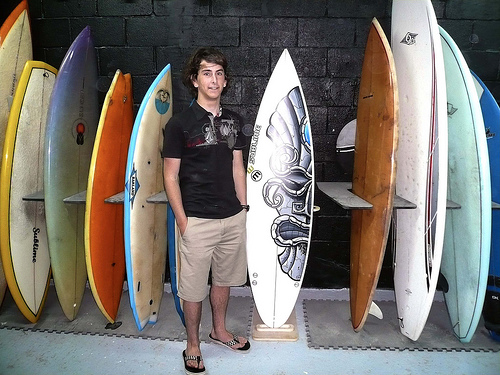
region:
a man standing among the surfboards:
[160, 49, 259, 372]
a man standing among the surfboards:
[28, 28, 413, 362]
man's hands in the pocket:
[153, 46, 257, 297]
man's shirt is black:
[143, 63, 273, 253]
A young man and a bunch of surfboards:
[26, 17, 404, 317]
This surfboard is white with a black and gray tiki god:
[249, 47, 317, 334]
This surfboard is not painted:
[328, 12, 402, 347]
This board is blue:
[470, 62, 498, 125]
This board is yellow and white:
[8, 58, 47, 327]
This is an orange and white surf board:
[1, 5, 46, 62]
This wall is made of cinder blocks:
[204, 3, 346, 42]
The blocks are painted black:
[282, 14, 348, 56]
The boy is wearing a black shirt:
[171, 54, 250, 156]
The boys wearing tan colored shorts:
[171, 76, 251, 301]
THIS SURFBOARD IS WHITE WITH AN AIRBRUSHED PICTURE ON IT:
[230, 42, 320, 349]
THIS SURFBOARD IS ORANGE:
[83, 62, 138, 332]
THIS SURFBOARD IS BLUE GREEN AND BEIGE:
[45, 27, 100, 337]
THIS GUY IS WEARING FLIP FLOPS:
[177, 320, 252, 371]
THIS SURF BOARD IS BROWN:
[330, 21, 397, 333]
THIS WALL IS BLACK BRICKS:
[0, 2, 496, 289]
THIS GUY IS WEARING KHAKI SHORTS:
[162, 210, 264, 318]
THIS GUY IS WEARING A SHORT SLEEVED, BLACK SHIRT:
[160, 100, 255, 221]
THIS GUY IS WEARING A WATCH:
[235, 190, 263, 220]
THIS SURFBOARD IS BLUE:
[468, 68, 498, 323]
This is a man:
[148, 66, 275, 357]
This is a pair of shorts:
[148, 190, 265, 270]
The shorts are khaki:
[165, 195, 292, 347]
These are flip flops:
[166, 341, 284, 373]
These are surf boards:
[184, 75, 499, 265]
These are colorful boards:
[13, 59, 245, 364]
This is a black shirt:
[161, 114, 219, 228]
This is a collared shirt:
[156, 101, 236, 133]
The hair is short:
[183, 26, 249, 123]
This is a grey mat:
[295, 291, 361, 370]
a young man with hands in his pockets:
[159, 49, 249, 373]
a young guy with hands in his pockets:
[167, 54, 248, 374]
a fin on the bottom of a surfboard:
[367, 302, 384, 322]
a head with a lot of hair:
[183, 46, 234, 98]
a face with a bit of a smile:
[196, 56, 226, 97]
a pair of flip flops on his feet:
[176, 327, 248, 372]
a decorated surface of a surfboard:
[245, 47, 311, 327]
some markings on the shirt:
[185, 115, 240, 150]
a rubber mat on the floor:
[301, 298, 496, 349]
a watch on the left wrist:
[239, 202, 252, 214]